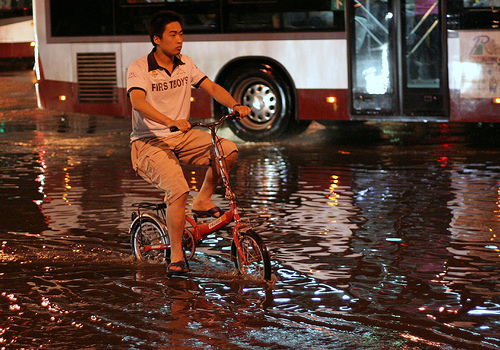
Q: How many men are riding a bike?
A: One.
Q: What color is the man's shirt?
A: White and black.